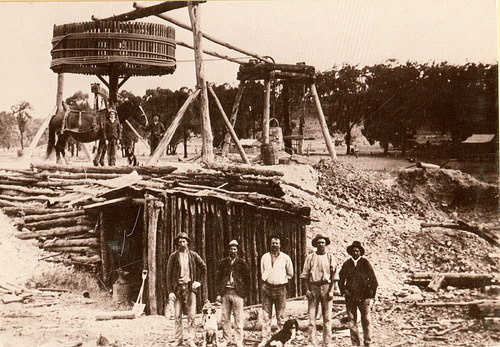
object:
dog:
[154, 288, 307, 346]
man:
[300, 233, 341, 347]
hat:
[311, 234, 331, 248]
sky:
[222, 7, 435, 60]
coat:
[214, 255, 252, 297]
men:
[338, 240, 379, 346]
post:
[263, 78, 272, 144]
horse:
[45, 95, 150, 164]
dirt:
[340, 167, 371, 191]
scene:
[37, 32, 465, 335]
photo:
[0, 0, 500, 347]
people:
[83, 227, 381, 342]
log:
[141, 15, 221, 166]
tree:
[331, 61, 472, 164]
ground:
[365, 166, 431, 219]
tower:
[246, 57, 306, 148]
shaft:
[146, 201, 165, 315]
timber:
[10, 166, 114, 242]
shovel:
[128, 268, 149, 318]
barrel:
[261, 142, 280, 166]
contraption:
[174, 162, 301, 229]